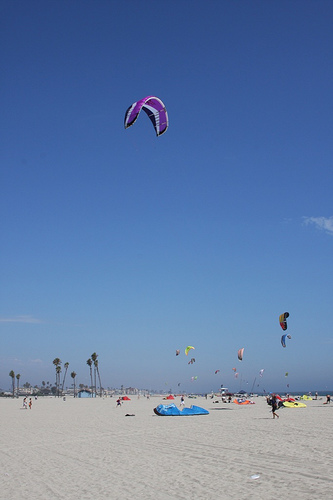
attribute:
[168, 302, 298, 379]
kites — curved 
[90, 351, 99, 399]
tree — brown , green , palm 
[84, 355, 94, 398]
tree — brown , green , palm 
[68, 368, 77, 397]
tree — brown , green , palm 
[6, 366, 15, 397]
tree — brown , green , palm 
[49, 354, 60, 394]
tree — brown , green , palm 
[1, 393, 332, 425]
sand — tan 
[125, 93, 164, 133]
stripe — black 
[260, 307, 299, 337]
parasail — red, yellow , black 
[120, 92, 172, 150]
kite — large, purple 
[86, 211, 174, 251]
sky — blue 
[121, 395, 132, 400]
kite — red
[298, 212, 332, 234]
white cloud — white 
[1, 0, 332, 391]
blue sky — blue 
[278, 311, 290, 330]
parachute — black , yellow , red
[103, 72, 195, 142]
kite — arched , purple 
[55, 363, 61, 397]
trees — cluster , tall , palm 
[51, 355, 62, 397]
trees — cluster , tall , palm 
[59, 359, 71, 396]
trees — cluster , tall , palm 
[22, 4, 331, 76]
sky — blue, clear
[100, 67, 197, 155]
parachute — blue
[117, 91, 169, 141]
para sail — red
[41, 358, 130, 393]
trees — palm 